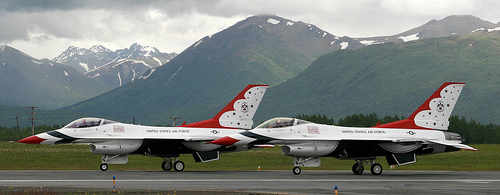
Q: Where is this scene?
A: An airport.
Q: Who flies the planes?
A: Pilots.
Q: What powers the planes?
A: Jet engines.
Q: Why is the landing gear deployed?
A: They are landed.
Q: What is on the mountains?
A: Some snow.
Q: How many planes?
A: 2.